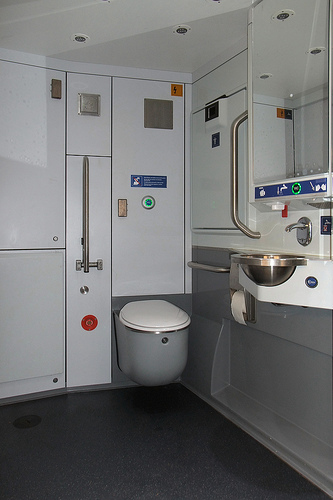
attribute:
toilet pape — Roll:
[226, 286, 248, 326]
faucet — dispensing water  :
[284, 216, 312, 247]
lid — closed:
[122, 296, 190, 329]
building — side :
[5, 7, 321, 495]